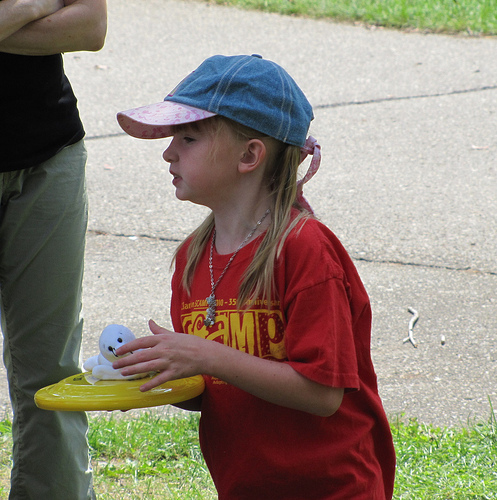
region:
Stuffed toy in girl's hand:
[93, 324, 144, 376]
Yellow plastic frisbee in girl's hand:
[38, 363, 202, 407]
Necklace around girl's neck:
[204, 212, 267, 328]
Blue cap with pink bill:
[122, 42, 306, 151]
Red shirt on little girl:
[157, 218, 405, 497]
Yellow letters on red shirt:
[178, 301, 301, 372]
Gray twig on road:
[399, 301, 439, 364]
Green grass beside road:
[11, 412, 491, 493]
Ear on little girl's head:
[243, 135, 265, 174]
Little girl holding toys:
[27, 42, 406, 498]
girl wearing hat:
[69, 56, 415, 499]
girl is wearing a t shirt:
[77, 54, 421, 483]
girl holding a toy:
[41, 62, 435, 494]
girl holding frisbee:
[66, 43, 438, 498]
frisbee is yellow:
[29, 375, 229, 410]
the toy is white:
[90, 304, 167, 377]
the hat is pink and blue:
[88, 47, 342, 172]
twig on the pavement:
[392, 294, 462, 374]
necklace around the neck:
[178, 191, 287, 349]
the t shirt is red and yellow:
[135, 209, 403, 492]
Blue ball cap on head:
[127, 39, 318, 151]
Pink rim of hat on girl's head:
[118, 98, 206, 135]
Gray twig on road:
[396, 304, 425, 355]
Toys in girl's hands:
[27, 319, 193, 409]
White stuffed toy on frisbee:
[88, 315, 144, 392]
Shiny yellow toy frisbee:
[35, 360, 218, 407]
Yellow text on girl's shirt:
[159, 294, 309, 370]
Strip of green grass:
[230, 1, 493, 42]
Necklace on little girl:
[190, 208, 273, 331]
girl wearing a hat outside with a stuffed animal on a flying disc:
[29, 47, 421, 498]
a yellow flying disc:
[27, 356, 243, 427]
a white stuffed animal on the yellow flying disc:
[71, 319, 161, 382]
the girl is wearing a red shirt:
[169, 226, 396, 494]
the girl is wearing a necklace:
[197, 241, 241, 332]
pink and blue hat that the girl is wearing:
[104, 52, 327, 162]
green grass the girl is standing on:
[398, 410, 486, 498]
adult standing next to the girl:
[0, 3, 105, 496]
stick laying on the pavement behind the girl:
[390, 289, 455, 363]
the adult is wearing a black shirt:
[0, 47, 94, 176]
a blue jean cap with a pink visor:
[117, 49, 314, 142]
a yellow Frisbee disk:
[33, 373, 204, 409]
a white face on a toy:
[84, 323, 150, 381]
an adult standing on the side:
[0, 0, 107, 328]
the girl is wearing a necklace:
[203, 216, 266, 329]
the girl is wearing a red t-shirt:
[170, 206, 395, 498]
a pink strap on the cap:
[295, 135, 322, 213]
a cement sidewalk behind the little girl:
[326, 24, 493, 224]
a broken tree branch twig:
[402, 305, 421, 351]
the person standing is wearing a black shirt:
[0, 3, 85, 169]